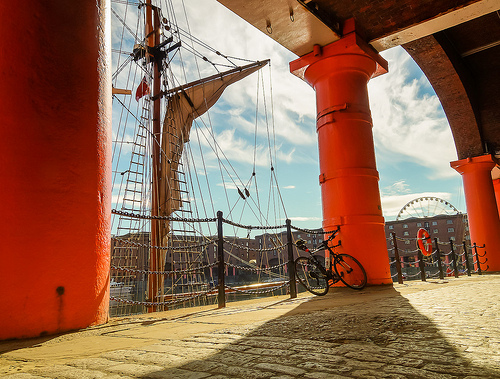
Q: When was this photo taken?
A: Outside, during the daytime.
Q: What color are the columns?
A: Orange.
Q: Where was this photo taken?
A: Underneath an overhang.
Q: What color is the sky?
A: Blue.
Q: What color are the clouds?
A: White.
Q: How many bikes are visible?
A: One.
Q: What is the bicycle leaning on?
A: Fence.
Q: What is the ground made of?
A: Bricks.